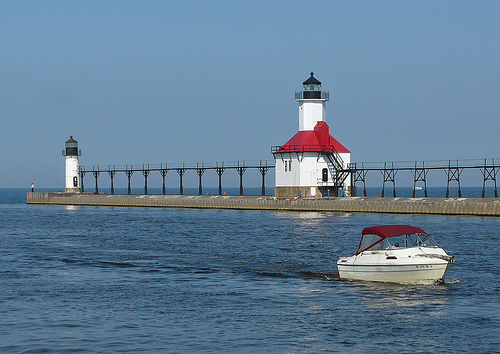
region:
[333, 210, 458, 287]
A boat on the water.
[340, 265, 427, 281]
color spots on bottom.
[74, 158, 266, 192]
A pier near the water.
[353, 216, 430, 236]
A red fabric roof.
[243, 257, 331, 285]
Waves in the water.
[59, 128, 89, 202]
A lighthous at the end of the pier.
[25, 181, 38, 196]
A man stands near waters edge.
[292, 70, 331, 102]
A second lighthouse.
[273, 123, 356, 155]
A red roof.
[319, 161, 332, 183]
A door entering the lighthouse.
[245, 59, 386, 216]
red and white lighthouse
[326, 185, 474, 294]
red and white boat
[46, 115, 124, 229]
tall white and black lighthouse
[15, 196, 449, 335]
clear blue rippled water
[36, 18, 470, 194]
cloudless blue sky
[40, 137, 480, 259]
long peir with lighthouses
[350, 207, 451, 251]
maroon top on a white boat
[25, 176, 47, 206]
person standing on the pier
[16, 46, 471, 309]
lighthouses and a boat on the water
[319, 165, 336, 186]
small black door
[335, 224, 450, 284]
a white boat with red top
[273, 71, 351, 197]
a red and white boat house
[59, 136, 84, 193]
a white and black lighthouse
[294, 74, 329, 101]
top of a lighthouse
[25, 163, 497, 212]
a long pier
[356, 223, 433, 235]
a boat's red top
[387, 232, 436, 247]
windshield of a white boat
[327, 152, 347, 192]
stairs on a lighthouse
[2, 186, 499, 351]
a blue ocean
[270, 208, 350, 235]
reflection of a lighthouse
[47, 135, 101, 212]
white and black lighthouse in photograph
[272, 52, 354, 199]
red and white building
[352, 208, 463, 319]
red and white boat in photo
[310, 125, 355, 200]
black ladder on buidling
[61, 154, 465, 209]
bridge connecting building and light house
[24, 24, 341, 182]
blue skies in photograph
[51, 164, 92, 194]
blakc door on white light house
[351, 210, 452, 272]
red canopy on white boat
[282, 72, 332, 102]
blacony at top of building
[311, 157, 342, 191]
blck door on white building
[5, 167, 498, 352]
a large body of blue water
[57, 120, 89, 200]
a round light house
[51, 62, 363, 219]
there are two light houses on pier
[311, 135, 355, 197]
steps going up side of building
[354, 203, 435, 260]
maroon colored top to boat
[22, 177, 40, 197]
person standing at the end of pier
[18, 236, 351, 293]
ripples left in water from boat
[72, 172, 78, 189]
the door to the light house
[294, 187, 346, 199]
short blue poles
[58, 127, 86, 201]
black and white building